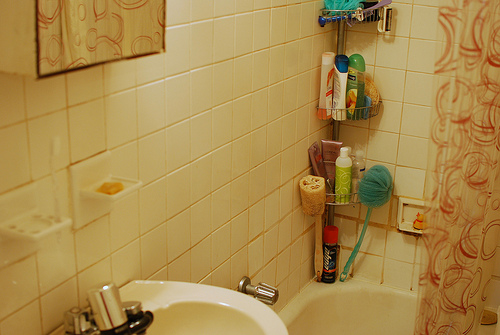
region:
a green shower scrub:
[326, 146, 403, 305]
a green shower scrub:
[335, 159, 377, 333]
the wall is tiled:
[177, 52, 239, 187]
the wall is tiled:
[178, 135, 289, 249]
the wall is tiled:
[220, 48, 301, 172]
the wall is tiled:
[108, 158, 227, 243]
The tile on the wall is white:
[173, 19, 290, 241]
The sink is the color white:
[118, 254, 293, 333]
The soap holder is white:
[78, 164, 143, 209]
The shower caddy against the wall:
[304, 0, 398, 287]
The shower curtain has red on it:
[421, 7, 498, 334]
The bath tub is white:
[278, 265, 440, 332]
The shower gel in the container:
[348, 50, 366, 112]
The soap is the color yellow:
[86, 168, 131, 196]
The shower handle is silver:
[237, 274, 285, 305]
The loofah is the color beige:
[293, 172, 332, 284]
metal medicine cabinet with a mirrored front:
[2, 0, 168, 80]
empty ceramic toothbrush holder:
[3, 207, 73, 244]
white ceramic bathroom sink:
[27, 277, 289, 334]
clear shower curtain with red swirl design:
[411, 0, 498, 333]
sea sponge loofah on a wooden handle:
[299, 172, 326, 282]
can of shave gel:
[318, 223, 340, 282]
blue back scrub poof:
[338, 164, 390, 283]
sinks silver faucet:
[63, 284, 153, 334]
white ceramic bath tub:
[277, 268, 499, 333]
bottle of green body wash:
[346, 51, 366, 119]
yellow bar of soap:
[96, 175, 123, 200]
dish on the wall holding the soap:
[66, 151, 141, 234]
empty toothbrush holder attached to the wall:
[1, 180, 74, 275]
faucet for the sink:
[62, 282, 159, 332]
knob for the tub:
[239, 272, 281, 307]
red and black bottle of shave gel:
[319, 222, 344, 286]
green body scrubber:
[340, 162, 395, 291]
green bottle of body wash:
[340, 50, 367, 123]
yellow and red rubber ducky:
[409, 207, 431, 230]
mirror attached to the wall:
[4, 0, 169, 80]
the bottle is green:
[345, 43, 368, 120]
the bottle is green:
[345, 45, 382, 137]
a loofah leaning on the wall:
[282, 153, 346, 297]